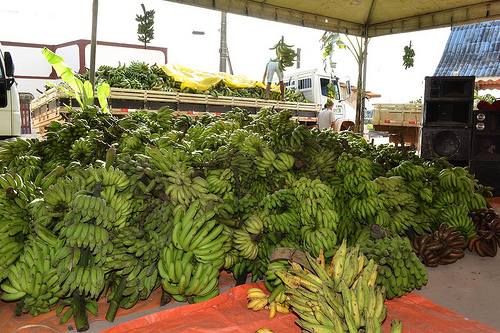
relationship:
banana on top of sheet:
[254, 298, 270, 312] [92, 276, 499, 333]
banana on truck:
[208, 89, 222, 101] [22, 66, 366, 143]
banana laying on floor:
[254, 298, 270, 312] [0, 241, 498, 332]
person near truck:
[314, 98, 340, 135] [22, 66, 366, 143]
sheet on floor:
[92, 276, 499, 333] [0, 241, 498, 332]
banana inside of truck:
[208, 89, 222, 101] [22, 66, 366, 143]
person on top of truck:
[259, 54, 289, 105] [22, 66, 366, 143]